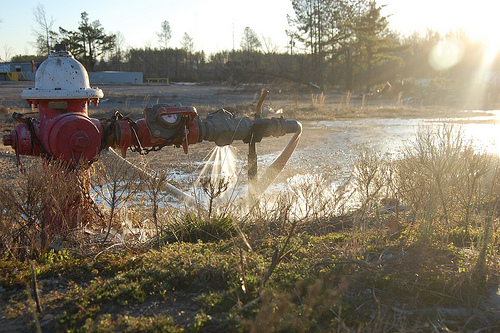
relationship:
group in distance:
[291, 0, 387, 100] [41, 13, 400, 55]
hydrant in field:
[8, 48, 102, 212] [68, 196, 443, 306]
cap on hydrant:
[32, 51, 105, 99] [8, 48, 102, 212]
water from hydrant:
[200, 145, 242, 189] [8, 48, 102, 212]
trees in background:
[193, 4, 397, 90] [109, 2, 409, 79]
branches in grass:
[214, 231, 330, 277] [120, 247, 241, 308]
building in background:
[92, 67, 144, 84] [109, 2, 409, 79]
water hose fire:
[200, 145, 242, 189] [251, 121, 305, 189]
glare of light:
[435, 33, 489, 65] [468, 0, 498, 66]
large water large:
[306, 115, 487, 189] [306, 115, 412, 191]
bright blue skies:
[164, 1, 268, 37] [145, 0, 276, 30]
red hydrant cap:
[10, 99, 98, 173] [18, 47, 106, 99]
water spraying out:
[200, 145, 242, 189] [202, 143, 239, 190]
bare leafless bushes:
[292, 166, 391, 209] [289, 163, 394, 209]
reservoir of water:
[323, 115, 405, 170] [200, 145, 242, 189]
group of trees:
[291, 1, 379, 100] [193, 4, 397, 90]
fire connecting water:
[251, 121, 305, 189] [200, 145, 242, 189]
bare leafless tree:
[27, 6, 56, 25] [32, 6, 56, 31]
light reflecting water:
[468, 0, 498, 66] [428, 117, 481, 139]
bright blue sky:
[164, 1, 268, 37] [136, 6, 261, 34]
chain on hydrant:
[147, 139, 175, 152] [8, 48, 102, 212]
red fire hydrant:
[10, 99, 98, 173] [8, 48, 102, 212]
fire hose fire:
[251, 121, 305, 189] [251, 121, 305, 189]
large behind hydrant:
[306, 115, 412, 191] [8, 48, 102, 212]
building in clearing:
[92, 67, 144, 84] [105, 75, 153, 104]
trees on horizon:
[193, 4, 397, 90] [118, 11, 266, 54]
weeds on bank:
[258, 184, 381, 262] [237, 194, 391, 283]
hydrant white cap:
[8, 48, 102, 212] [32, 51, 105, 99]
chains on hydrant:
[68, 179, 100, 218] [8, 48, 102, 212]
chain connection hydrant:
[147, 139, 175, 152] [8, 48, 102, 212]